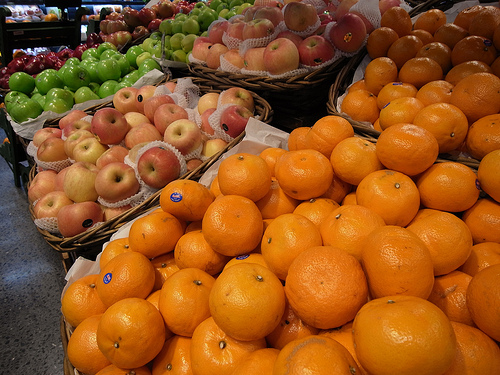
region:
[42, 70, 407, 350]
fruits in the baskets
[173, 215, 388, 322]
oranges in the basket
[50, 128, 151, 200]
apples in the basket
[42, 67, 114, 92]
apples in the basket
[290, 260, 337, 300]
the orange is orange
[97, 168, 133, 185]
the apple is red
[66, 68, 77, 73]
the apple is green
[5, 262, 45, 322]
the table is granite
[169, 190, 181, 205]
sticker on the orange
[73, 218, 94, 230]
sticker on the apple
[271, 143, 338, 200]
The orange is unpeeled.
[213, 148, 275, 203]
The orange is unpeeled.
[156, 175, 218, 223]
The orange is unpeeled.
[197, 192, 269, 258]
The orange is unpeeled.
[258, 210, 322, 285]
The orange is unpeeled.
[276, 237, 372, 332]
The orange is unpeeled.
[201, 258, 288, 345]
The orange is unpeeled.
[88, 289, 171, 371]
The orange is unpeeled.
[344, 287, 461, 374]
The orange is unpeeled.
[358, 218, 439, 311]
The orange is unpeeled.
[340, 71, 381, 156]
Big giraffe standing in the yard with trees.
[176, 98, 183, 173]
Big giraffe standing in the yard with trees.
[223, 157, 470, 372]
oranges in a market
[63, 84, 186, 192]
apples in a bin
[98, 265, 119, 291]
sticker on an orange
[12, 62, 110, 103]
green apples in a bin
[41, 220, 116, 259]
brown basket with fruit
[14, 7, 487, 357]
fruit at a market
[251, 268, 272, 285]
stem of an orange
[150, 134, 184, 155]
paper cup of an apple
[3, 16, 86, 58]
wooden table in the background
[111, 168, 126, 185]
stem of an apple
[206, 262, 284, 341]
orange on display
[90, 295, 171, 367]
orange on the display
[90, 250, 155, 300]
orange on the display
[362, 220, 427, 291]
orange on the display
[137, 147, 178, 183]
apple on the display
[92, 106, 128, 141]
apple on the display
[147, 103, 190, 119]
apple on the display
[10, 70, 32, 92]
apple on the display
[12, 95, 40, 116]
apple on the display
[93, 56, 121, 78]
apple on the display